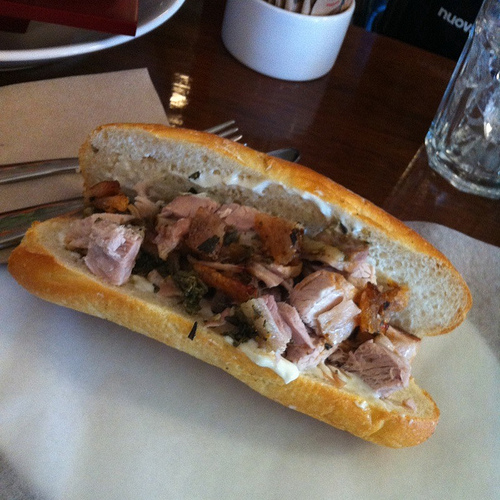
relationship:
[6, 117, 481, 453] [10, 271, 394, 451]
bread has edge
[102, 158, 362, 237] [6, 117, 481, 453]
cream on bread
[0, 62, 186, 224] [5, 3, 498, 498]
cloth on table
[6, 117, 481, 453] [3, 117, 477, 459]
bread on sandwich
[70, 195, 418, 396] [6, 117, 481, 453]
meat on bread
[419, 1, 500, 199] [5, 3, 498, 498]
mug on table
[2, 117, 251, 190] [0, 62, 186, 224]
fork on cloth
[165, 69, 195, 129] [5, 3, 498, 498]
light reflected on table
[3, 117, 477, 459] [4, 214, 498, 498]
sandwich on napkin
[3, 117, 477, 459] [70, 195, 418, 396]
sandwich has meat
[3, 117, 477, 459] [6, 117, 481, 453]
sandwich has bread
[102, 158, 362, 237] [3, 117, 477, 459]
cream on sandwich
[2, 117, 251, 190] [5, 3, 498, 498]
fork on table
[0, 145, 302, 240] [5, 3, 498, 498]
spoon on table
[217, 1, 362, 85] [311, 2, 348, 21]
condiment dish holds sugar packet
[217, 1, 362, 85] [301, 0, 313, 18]
condiment dish holds sugar packet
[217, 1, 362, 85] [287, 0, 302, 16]
condiment dish holds sugar packet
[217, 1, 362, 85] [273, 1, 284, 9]
condiment dish holds sugar packet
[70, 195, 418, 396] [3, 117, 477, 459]
meat on sandwich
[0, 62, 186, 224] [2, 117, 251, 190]
napkin under fork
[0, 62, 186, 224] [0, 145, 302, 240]
napkin under spoon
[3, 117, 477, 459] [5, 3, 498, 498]
sandwich on table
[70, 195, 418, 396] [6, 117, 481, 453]
meat between bread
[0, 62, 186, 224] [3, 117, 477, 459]
cloth behind sandwich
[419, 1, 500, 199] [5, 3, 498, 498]
glass reflected on table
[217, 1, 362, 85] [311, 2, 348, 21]
condiment dish has sugar packet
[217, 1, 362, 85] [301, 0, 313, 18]
condiment dish has sugar packet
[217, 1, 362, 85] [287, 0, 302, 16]
condiment dish has sugar packet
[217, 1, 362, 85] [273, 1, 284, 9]
condiment dish has sugar packet